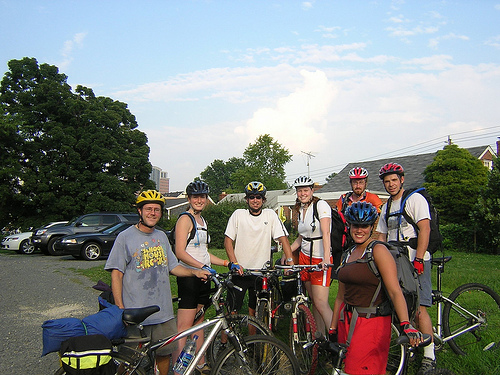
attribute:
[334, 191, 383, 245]
shirt — is red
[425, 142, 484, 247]
tree — green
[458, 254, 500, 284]
grass — green, grassy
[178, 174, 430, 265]
people — posing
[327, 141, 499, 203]
building — black, gray, grey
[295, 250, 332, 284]
shorts — red, white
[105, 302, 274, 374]
bicycle — silvery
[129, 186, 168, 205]
helmet — yellow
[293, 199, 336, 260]
shirt — white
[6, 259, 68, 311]
area — paved, grey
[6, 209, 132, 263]
vehicles — parked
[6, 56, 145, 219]
tree — large, green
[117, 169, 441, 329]
people — standing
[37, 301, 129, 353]
bundle — blue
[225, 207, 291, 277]
tee shirt — white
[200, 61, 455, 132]
cloud — white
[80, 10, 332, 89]
sky — blue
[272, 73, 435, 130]
clouds — white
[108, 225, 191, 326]
shirt — gray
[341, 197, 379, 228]
helmet — blue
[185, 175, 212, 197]
helmet — black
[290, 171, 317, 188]
helmet — white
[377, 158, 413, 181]
helmet — red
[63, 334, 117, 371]
bag — green, black